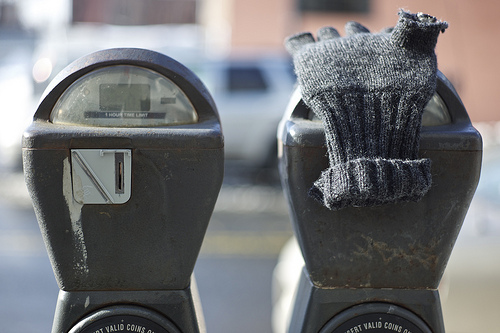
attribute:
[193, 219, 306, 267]
line — yellow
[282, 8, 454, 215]
glove — black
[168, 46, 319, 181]
car — blurry